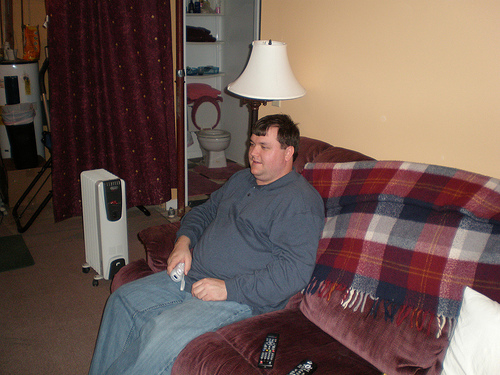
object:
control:
[287, 358, 318, 373]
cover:
[190, 97, 224, 130]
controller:
[258, 334, 280, 369]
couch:
[110, 136, 498, 375]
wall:
[255, 0, 500, 185]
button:
[247, 193, 251, 196]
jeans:
[87, 269, 250, 374]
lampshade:
[226, 39, 305, 102]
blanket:
[302, 159, 500, 340]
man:
[91, 113, 325, 374]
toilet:
[191, 95, 232, 168]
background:
[0, 0, 500, 374]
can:
[0, 103, 39, 170]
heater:
[1, 59, 47, 166]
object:
[78, 167, 128, 286]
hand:
[157, 236, 204, 278]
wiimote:
[169, 262, 186, 290]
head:
[247, 114, 300, 180]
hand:
[167, 240, 192, 277]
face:
[248, 128, 282, 180]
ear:
[285, 146, 295, 162]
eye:
[260, 144, 269, 151]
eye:
[249, 141, 255, 149]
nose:
[249, 145, 261, 159]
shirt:
[175, 168, 324, 315]